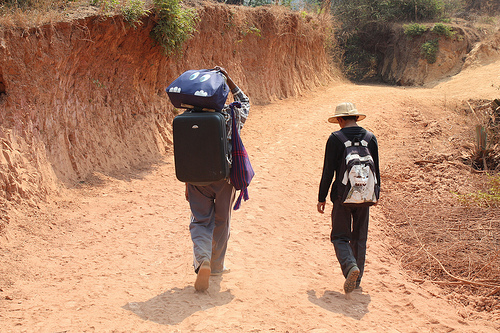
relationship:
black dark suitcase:
[173, 114, 228, 180] [173, 115, 229, 180]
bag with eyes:
[168, 68, 229, 110] [188, 68, 213, 85]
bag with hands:
[168, 68, 229, 110] [169, 85, 210, 98]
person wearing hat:
[313, 99, 383, 295] [328, 102, 366, 122]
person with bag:
[313, 99, 383, 295] [334, 129, 379, 209]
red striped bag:
[235, 132, 251, 195] [232, 106, 255, 211]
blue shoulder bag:
[233, 112, 255, 211] [232, 106, 255, 211]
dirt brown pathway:
[9, 74, 495, 325] [21, 77, 400, 332]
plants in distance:
[345, 2, 444, 80] [195, 5, 499, 77]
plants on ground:
[345, 2, 444, 80] [351, 21, 497, 86]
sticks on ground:
[395, 202, 499, 294] [12, 72, 458, 332]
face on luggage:
[188, 71, 214, 87] [168, 68, 229, 110]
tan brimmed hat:
[328, 102, 366, 122] [328, 102, 366, 122]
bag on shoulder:
[232, 106, 255, 211] [226, 105, 254, 130]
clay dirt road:
[9, 74, 495, 325] [21, 77, 400, 332]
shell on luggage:
[174, 118, 226, 183] [173, 115, 229, 180]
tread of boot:
[195, 289, 219, 332] [193, 260, 211, 294]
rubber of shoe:
[196, 267, 211, 290] [193, 260, 211, 294]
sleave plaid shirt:
[229, 87, 251, 129] [226, 88, 253, 135]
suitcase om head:
[168, 68, 229, 110] [193, 72, 229, 111]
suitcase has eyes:
[168, 68, 229, 110] [188, 68, 213, 85]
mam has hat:
[313, 99, 383, 295] [328, 102, 366, 122]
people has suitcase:
[168, 64, 255, 293] [173, 115, 229, 180]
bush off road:
[345, 2, 444, 80] [21, 77, 400, 332]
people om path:
[166, 68, 394, 293] [21, 77, 400, 332]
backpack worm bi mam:
[334, 129, 379, 209] [313, 99, 383, 295]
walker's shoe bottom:
[313, 99, 383, 295] [346, 267, 360, 293]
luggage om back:
[173, 115, 229, 180] [171, 110, 235, 187]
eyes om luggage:
[188, 68, 213, 85] [168, 68, 229, 110]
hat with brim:
[328, 102, 366, 122] [327, 110, 369, 125]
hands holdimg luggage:
[211, 65, 226, 75] [168, 68, 229, 110]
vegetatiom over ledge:
[133, 4, 440, 71] [6, 14, 452, 92]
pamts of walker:
[330, 206, 371, 272] [313, 99, 383, 295]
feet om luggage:
[168, 86, 211, 98] [168, 68, 229, 110]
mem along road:
[166, 68, 394, 293] [21, 77, 400, 332]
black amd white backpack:
[338, 129, 379, 205] [334, 129, 379, 209]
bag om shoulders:
[168, 68, 229, 110] [198, 106, 250, 134]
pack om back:
[334, 129, 379, 209] [334, 130, 379, 207]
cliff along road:
[4, 4, 328, 46] [21, 77, 400, 332]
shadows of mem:
[126, 283, 368, 325] [166, 68, 394, 293]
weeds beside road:
[133, 4, 440, 71] [21, 77, 400, 332]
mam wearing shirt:
[313, 99, 383, 295] [317, 126, 386, 202]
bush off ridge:
[133, 4, 440, 71] [4, 4, 328, 46]